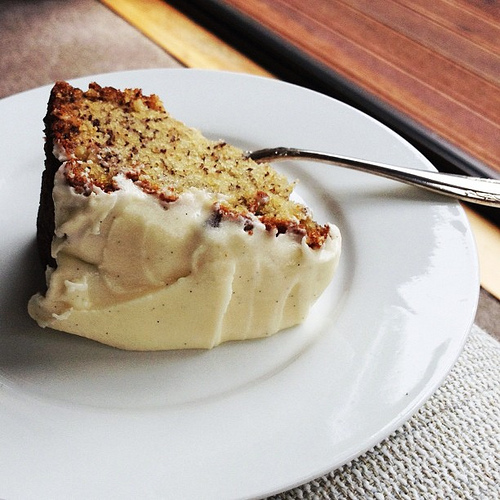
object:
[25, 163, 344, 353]
frosting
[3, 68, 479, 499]
plate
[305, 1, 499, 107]
floor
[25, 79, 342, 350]
cake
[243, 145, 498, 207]
utensil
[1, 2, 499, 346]
table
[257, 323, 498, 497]
mat